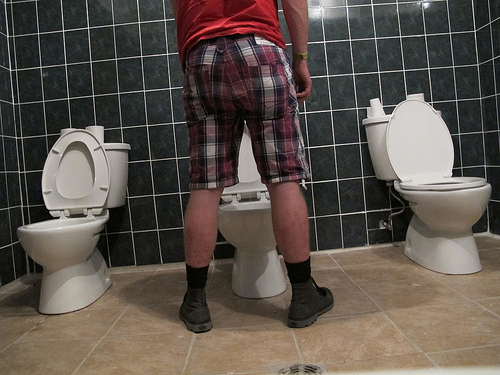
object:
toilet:
[0, 0, 500, 375]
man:
[170, 0, 333, 334]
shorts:
[181, 34, 311, 190]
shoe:
[286, 276, 334, 328]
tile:
[63, 30, 90, 60]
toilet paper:
[366, 97, 386, 118]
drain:
[275, 364, 327, 374]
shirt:
[170, 0, 288, 71]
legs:
[182, 186, 222, 269]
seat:
[39, 126, 109, 216]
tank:
[361, 92, 455, 184]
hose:
[382, 181, 406, 230]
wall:
[13, 6, 496, 269]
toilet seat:
[39, 128, 112, 216]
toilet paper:
[59, 125, 105, 144]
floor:
[0, 230, 500, 375]